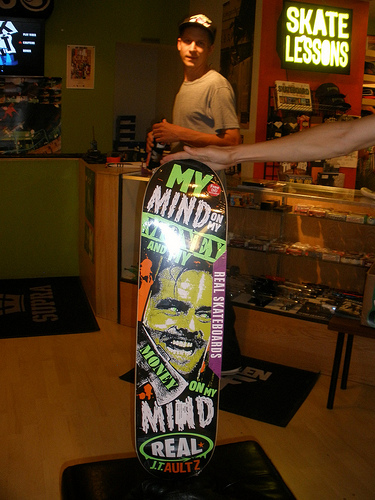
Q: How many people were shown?
A: One.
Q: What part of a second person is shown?
A: Arm.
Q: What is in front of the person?
A: Surfboard.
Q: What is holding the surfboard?
A: Hand.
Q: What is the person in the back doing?
A: Standing.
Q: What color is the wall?
A: Green.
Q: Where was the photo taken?
A: At a skate shop.